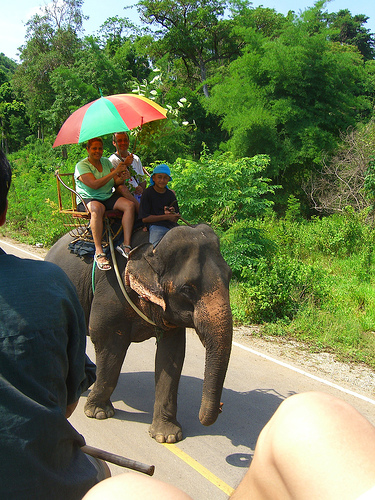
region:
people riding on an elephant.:
[5, 75, 331, 420]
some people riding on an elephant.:
[25, 72, 303, 376]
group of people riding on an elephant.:
[3, 78, 283, 402]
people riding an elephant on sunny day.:
[39, 79, 270, 354]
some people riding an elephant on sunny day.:
[25, 62, 284, 378]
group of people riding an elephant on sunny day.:
[18, 53, 275, 387]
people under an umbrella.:
[46, 72, 178, 162]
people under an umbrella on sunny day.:
[44, 88, 165, 180]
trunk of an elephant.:
[189, 302, 232, 431]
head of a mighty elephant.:
[124, 227, 237, 343]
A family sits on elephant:
[30, 69, 240, 449]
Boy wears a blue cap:
[135, 150, 187, 258]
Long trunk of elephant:
[191, 291, 238, 430]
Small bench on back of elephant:
[46, 165, 91, 246]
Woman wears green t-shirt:
[61, 130, 137, 260]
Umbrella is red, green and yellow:
[34, 81, 174, 148]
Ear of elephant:
[112, 250, 168, 310]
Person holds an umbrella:
[50, 82, 170, 257]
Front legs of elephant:
[84, 327, 194, 456]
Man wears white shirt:
[106, 128, 149, 193]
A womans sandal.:
[94, 246, 112, 272]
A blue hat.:
[150, 161, 178, 179]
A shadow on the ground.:
[223, 443, 260, 472]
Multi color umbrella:
[59, 98, 164, 129]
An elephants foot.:
[147, 405, 191, 443]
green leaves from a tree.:
[215, 65, 311, 137]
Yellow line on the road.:
[184, 439, 225, 491]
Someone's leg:
[256, 395, 361, 495]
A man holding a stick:
[76, 422, 165, 483]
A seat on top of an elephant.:
[52, 169, 93, 239]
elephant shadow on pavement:
[76, 337, 328, 498]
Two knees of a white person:
[68, 386, 373, 499]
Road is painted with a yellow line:
[170, 442, 233, 498]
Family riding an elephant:
[57, 126, 190, 273]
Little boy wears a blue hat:
[137, 155, 188, 247]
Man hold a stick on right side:
[2, 162, 161, 496]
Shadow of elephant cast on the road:
[118, 365, 279, 464]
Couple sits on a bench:
[46, 131, 154, 278]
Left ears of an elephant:
[119, 244, 174, 316]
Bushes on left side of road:
[197, 73, 365, 331]